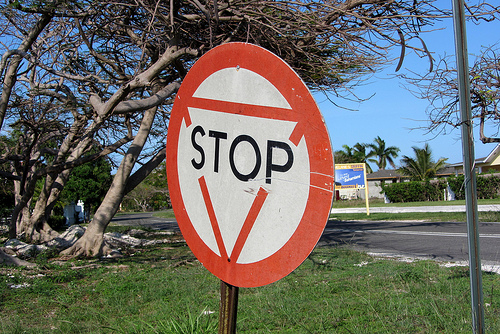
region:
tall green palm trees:
[328, 136, 445, 178]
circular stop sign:
[165, 46, 345, 291]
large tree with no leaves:
[18, 0, 340, 244]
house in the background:
[365, 145, 497, 200]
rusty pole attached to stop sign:
[218, 275, 250, 332]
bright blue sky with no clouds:
[23, 15, 473, 165]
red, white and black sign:
[145, 41, 338, 271]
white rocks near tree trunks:
[8, 215, 143, 269]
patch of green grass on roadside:
[21, 238, 458, 324]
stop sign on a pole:
[148, 17, 341, 329]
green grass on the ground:
[291, 282, 421, 312]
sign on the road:
[333, 147, 378, 231]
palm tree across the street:
[393, 142, 450, 203]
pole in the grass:
[447, 10, 498, 312]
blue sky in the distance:
[337, 78, 416, 135]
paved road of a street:
[392, 220, 477, 260]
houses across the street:
[376, 140, 496, 205]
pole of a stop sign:
[208, 278, 255, 331]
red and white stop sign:
[160, 35, 335, 285]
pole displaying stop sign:
[220, 285, 235, 330]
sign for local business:
[325, 155, 370, 215]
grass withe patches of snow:
[0, 230, 495, 325]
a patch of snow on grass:
[195, 305, 215, 310]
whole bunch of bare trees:
[0, 0, 499, 275]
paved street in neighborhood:
[115, 205, 496, 268]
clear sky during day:
[1, 0, 498, 174]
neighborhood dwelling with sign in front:
[364, 142, 499, 202]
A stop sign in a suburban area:
[160, 35, 337, 332]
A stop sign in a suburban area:
[160, 31, 330, 328]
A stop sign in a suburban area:
[155, 35, 345, 330]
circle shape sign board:
[166, 38, 335, 289]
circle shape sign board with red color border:
[149, 44, 331, 294]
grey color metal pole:
[442, 3, 498, 323]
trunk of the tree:
[91, 180, 123, 250]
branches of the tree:
[101, 13, 272, 36]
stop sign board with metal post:
[160, 47, 340, 330]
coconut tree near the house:
[403, 136, 440, 196]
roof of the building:
[378, 167, 456, 177]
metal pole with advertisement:
[335, 158, 369, 222]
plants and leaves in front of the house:
[381, 176, 448, 201]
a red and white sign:
[138, 29, 345, 284]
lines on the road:
[360, 211, 482, 247]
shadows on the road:
[346, 208, 448, 248]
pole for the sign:
[207, 275, 242, 330]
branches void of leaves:
[403, 49, 496, 151]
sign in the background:
[332, 160, 376, 200]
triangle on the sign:
[165, 85, 315, 269]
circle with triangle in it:
[144, 32, 343, 294]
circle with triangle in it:
[147, 32, 355, 300]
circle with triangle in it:
[140, 31, 355, 293]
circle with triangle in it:
[144, 30, 359, 290]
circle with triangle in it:
[150, 37, 343, 299]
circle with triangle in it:
[155, 31, 340, 290]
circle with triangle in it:
[143, 23, 353, 293]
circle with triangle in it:
[151, 33, 348, 297]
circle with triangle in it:
[155, 33, 351, 291]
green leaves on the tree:
[418, 142, 431, 173]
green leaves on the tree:
[373, 124, 390, 163]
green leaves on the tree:
[341, 133, 352, 151]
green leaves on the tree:
[80, 178, 102, 192]